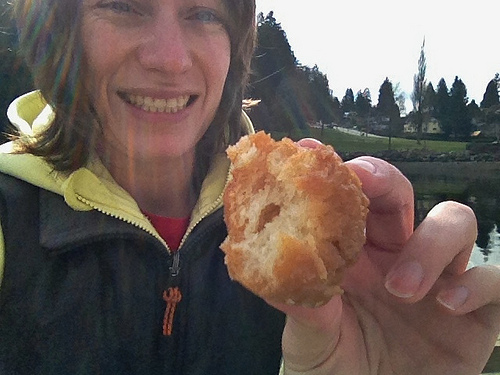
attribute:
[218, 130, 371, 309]
cake — brown, golden, toasted, bready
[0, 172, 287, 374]
jacket — black, grey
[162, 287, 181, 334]
rope — brown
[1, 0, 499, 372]
lady — smiling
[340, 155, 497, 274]
water — blue, small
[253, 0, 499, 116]
sky — white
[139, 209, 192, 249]
shirt — red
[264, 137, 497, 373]
hand — long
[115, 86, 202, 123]
smile — wide, toothy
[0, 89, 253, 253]
insert — yellow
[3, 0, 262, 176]
hair — short, dirty blonde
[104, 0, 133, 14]
eye — blue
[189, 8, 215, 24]
eye — blue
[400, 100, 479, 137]
house — large, yellow